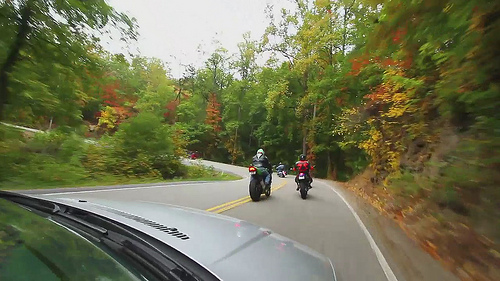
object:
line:
[71, 190, 101, 194]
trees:
[132, 60, 174, 114]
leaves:
[352, 6, 487, 104]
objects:
[234, 130, 334, 209]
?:
[453, 155, 463, 161]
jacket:
[250, 154, 274, 170]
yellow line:
[220, 202, 242, 212]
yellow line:
[222, 200, 237, 206]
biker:
[252, 149, 273, 188]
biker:
[292, 155, 314, 190]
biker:
[275, 161, 284, 172]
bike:
[249, 164, 273, 201]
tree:
[3, 3, 67, 91]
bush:
[109, 110, 177, 172]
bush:
[4, 121, 90, 180]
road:
[181, 186, 220, 204]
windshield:
[0, 191, 160, 281]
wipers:
[1, 192, 197, 281]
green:
[123, 120, 166, 151]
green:
[314, 68, 339, 141]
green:
[447, 150, 478, 172]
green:
[27, 65, 69, 91]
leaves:
[200, 89, 223, 131]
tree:
[193, 47, 231, 160]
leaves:
[3, 2, 108, 106]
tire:
[249, 179, 261, 201]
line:
[365, 240, 399, 278]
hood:
[21, 194, 339, 281]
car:
[0, 188, 336, 281]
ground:
[343, 226, 382, 275]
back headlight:
[248, 166, 256, 172]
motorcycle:
[275, 168, 287, 178]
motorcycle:
[289, 165, 316, 200]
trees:
[296, 0, 355, 179]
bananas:
[337, 170, 455, 270]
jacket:
[292, 160, 315, 174]